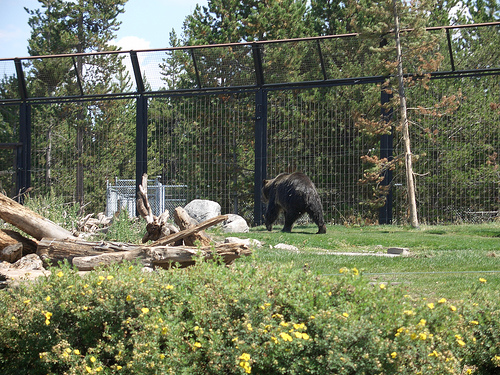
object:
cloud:
[79, 31, 176, 98]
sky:
[3, 1, 206, 99]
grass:
[2, 219, 498, 374]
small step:
[384, 242, 419, 257]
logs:
[76, 248, 207, 260]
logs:
[0, 202, 57, 236]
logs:
[162, 215, 232, 235]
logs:
[54, 240, 91, 256]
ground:
[255, 235, 497, 267]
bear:
[260, 172, 328, 235]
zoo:
[61, 33, 466, 334]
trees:
[20, 0, 125, 228]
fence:
[0, 20, 499, 225]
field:
[275, 230, 485, 359]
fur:
[282, 174, 307, 199]